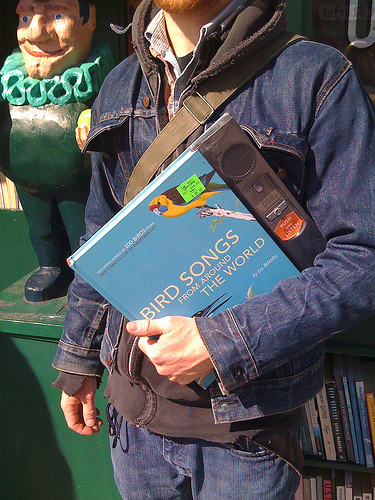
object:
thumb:
[125, 317, 164, 336]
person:
[56, 0, 374, 500]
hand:
[127, 314, 215, 387]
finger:
[58, 398, 96, 437]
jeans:
[105, 403, 299, 499]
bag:
[122, 34, 306, 210]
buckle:
[181, 91, 213, 123]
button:
[140, 94, 150, 109]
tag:
[177, 173, 207, 205]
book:
[315, 384, 336, 461]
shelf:
[290, 321, 375, 499]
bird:
[148, 165, 235, 220]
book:
[65, 113, 326, 388]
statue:
[1, 1, 116, 302]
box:
[0, 264, 115, 498]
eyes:
[53, 13, 62, 20]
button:
[263, 199, 292, 223]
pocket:
[82, 114, 140, 204]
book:
[324, 372, 349, 463]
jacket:
[51, 2, 373, 423]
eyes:
[20, 12, 31, 22]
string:
[105, 403, 130, 452]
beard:
[152, 0, 203, 15]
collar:
[144, 3, 240, 115]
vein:
[177, 355, 208, 374]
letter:
[137, 305, 153, 320]